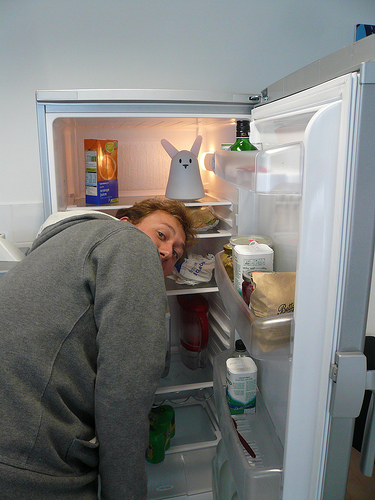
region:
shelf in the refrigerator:
[176, 371, 206, 380]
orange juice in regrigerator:
[83, 131, 124, 203]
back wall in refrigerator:
[134, 127, 157, 161]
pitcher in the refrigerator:
[178, 299, 204, 370]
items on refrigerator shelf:
[219, 243, 279, 308]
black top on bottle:
[225, 119, 257, 139]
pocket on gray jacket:
[66, 429, 103, 470]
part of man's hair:
[143, 198, 169, 207]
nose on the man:
[157, 241, 172, 260]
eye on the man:
[154, 228, 168, 239]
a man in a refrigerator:
[34, 145, 225, 358]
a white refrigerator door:
[185, 116, 353, 493]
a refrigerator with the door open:
[54, 98, 355, 381]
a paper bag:
[242, 261, 295, 336]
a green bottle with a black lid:
[230, 117, 257, 165]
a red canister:
[171, 295, 212, 371]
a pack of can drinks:
[144, 400, 180, 462]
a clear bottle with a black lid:
[217, 336, 256, 415]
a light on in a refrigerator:
[197, 142, 219, 181]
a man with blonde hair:
[142, 183, 193, 271]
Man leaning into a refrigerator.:
[31, 198, 202, 494]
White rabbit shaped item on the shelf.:
[156, 137, 216, 202]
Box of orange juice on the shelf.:
[78, 130, 123, 190]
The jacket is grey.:
[15, 263, 135, 471]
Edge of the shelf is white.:
[163, 380, 217, 399]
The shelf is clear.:
[182, 405, 218, 452]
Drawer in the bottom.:
[148, 454, 220, 499]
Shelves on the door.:
[214, 150, 310, 490]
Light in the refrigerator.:
[182, 132, 215, 182]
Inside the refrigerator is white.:
[31, 89, 367, 486]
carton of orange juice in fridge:
[76, 127, 154, 234]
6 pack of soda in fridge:
[144, 399, 185, 489]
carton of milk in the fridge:
[222, 338, 273, 429]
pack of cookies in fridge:
[233, 263, 309, 380]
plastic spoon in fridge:
[227, 413, 280, 466]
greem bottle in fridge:
[216, 110, 282, 206]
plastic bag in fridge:
[158, 251, 251, 290]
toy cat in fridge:
[152, 122, 254, 225]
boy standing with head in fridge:
[13, 176, 214, 494]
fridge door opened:
[0, 16, 372, 498]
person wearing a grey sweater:
[58, 236, 141, 346]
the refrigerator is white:
[317, 189, 370, 308]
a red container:
[182, 301, 212, 350]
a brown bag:
[252, 272, 288, 305]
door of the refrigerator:
[310, 138, 374, 298]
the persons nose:
[159, 241, 172, 260]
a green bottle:
[233, 139, 253, 152]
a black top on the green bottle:
[232, 120, 252, 137]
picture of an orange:
[98, 155, 117, 179]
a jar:
[219, 248, 231, 269]